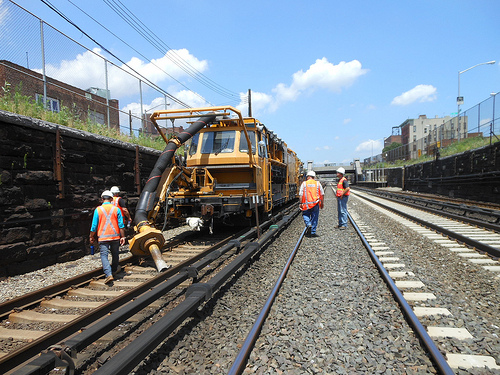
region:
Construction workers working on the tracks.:
[92, 168, 188, 293]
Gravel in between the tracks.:
[306, 243, 373, 348]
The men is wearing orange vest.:
[297, 168, 359, 231]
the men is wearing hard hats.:
[68, 170, 134, 274]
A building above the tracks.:
[17, 56, 155, 127]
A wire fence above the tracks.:
[23, 13, 168, 131]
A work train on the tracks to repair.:
[169, 91, 339, 218]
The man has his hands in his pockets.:
[328, 155, 355, 237]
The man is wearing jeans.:
[291, 199, 341, 240]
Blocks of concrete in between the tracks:
[388, 250, 458, 348]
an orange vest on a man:
[300, 180, 320, 211]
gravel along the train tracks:
[290, 205, 375, 371]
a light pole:
[455, 50, 490, 135]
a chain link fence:
[375, 90, 495, 170]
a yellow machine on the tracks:
[105, 107, 310, 298]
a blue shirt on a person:
[85, 202, 125, 232]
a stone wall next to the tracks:
[3, 106, 160, 263]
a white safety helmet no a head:
[334, 166, 348, 175]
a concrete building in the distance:
[380, 107, 469, 162]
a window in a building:
[28, 89, 66, 118]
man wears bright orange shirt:
[285, 177, 317, 216]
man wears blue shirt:
[95, 203, 128, 243]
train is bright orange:
[173, 74, 298, 231]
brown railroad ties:
[24, 238, 149, 353]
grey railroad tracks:
[49, 236, 226, 371]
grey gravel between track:
[223, 213, 389, 355]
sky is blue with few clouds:
[163, 1, 383, 193]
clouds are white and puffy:
[28, 32, 288, 110]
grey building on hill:
[370, 84, 490, 159]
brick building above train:
[2, 67, 148, 152]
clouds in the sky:
[288, 63, 376, 93]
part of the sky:
[370, 10, 462, 52]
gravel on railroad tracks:
[316, 249, 366, 349]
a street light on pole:
[455, 52, 497, 93]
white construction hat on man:
[333, 163, 350, 174]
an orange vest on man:
[305, 180, 319, 204]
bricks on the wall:
[11, 170, 57, 202]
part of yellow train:
[258, 130, 295, 175]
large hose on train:
[175, 118, 212, 135]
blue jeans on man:
[102, 252, 124, 267]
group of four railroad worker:
[82, 163, 364, 288]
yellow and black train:
[131, 104, 307, 224]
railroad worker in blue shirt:
[89, 189, 127, 290]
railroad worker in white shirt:
[296, 173, 328, 240]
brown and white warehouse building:
[380, 118, 484, 163]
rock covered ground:
[301, 240, 367, 369]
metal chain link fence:
[362, 84, 494, 169]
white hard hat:
[303, 168, 316, 178]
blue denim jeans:
[98, 240, 125, 277]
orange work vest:
[94, 203, 121, 245]